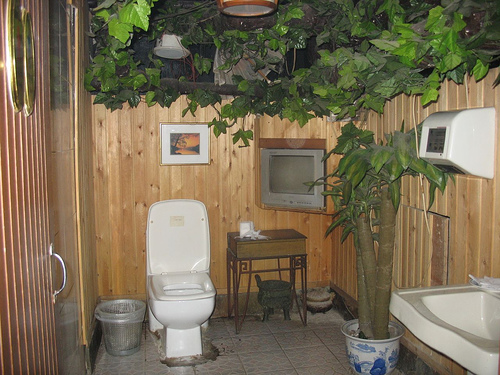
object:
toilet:
[145, 198, 217, 358]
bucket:
[93, 299, 145, 356]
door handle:
[49, 242, 67, 304]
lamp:
[153, 33, 190, 59]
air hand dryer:
[419, 106, 495, 180]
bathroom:
[77, 34, 500, 375]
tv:
[260, 148, 325, 207]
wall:
[93, 69, 500, 299]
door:
[0, 0, 59, 375]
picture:
[162, 125, 209, 164]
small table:
[226, 228, 308, 334]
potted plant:
[303, 121, 456, 341]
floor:
[93, 309, 351, 375]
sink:
[388, 282, 500, 375]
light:
[216, 0, 277, 17]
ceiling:
[81, 0, 94, 7]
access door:
[394, 204, 450, 288]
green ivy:
[89, 0, 500, 147]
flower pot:
[340, 318, 405, 375]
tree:
[84, 0, 499, 340]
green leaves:
[113, 0, 154, 31]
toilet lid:
[146, 198, 211, 275]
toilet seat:
[151, 272, 217, 301]